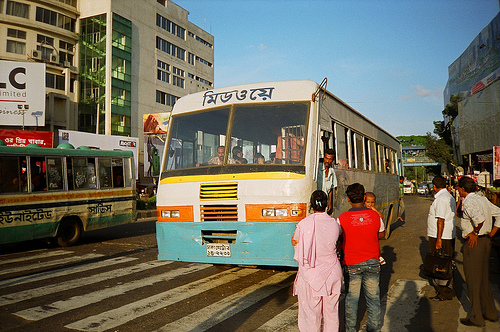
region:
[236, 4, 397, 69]
this is the sky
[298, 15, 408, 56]
the sky is blue in color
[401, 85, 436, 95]
the sky has some clouds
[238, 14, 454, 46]
most of the sky is clear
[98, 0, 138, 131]
this is a building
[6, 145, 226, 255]
these are two buses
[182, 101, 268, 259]
the bus is big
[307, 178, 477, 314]
people waiting to board the bus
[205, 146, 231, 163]
this is the bus driver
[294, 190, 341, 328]
A woman dressed in pink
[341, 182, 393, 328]
A man holding a baby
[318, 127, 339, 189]
A man leaving the bus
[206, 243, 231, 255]
A license plate on a bus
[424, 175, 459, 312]
A man in a white shirt holding a bag.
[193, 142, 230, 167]
Man driving the bus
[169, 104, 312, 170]
The front window of the bus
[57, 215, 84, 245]
The tire of a bus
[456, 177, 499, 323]
A man in brown pants waiting for a bus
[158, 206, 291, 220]
The headlights of the bus.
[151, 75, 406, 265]
bus on street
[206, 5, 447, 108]
sky appears blue and mostly clear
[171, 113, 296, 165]
people inside bus seen through front windows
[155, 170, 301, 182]
yellow line on front of bus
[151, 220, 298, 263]
thick blue stripe on front of bus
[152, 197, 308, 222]
area behind bus' headlights is orange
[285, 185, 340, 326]
woman wearing a pink outfit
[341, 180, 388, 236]
small child looking back over man's shoulder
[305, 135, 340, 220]
man leaning out of bus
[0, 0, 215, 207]
large modern-looking building near bus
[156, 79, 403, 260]
the bus is low the ground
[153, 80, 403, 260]
the bus is white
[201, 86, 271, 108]
the bus has foreign letters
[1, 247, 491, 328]
the street has white lines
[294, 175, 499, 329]
the people are standing on the street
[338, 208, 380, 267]
the man wears a red shirt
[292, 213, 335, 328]
the woman wears a pink outfit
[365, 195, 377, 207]
the man holds the baby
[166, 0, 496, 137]
the sky is blue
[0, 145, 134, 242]
the bus is green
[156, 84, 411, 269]
Multi-colored bus.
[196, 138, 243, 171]
Driver on the bus.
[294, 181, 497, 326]
People waiting to get on the bus.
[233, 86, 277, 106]
Name of bus company on the bus.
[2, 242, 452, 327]
Striped crossing lines on the road.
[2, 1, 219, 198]
Buildings in the background.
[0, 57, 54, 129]
Advertisements on the buildings.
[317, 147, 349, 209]
Man hanging out of bus.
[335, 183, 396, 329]
Red-shirted man waiting for bus.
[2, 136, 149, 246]
Another bus driving by.